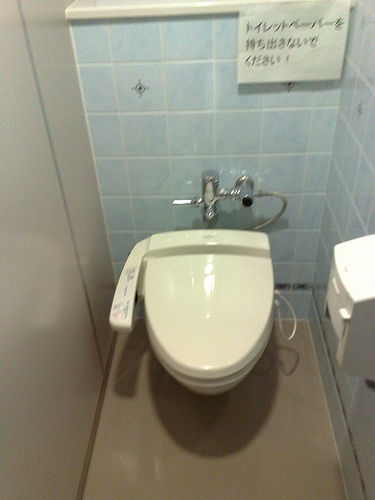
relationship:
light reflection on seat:
[195, 244, 222, 293] [138, 247, 275, 395]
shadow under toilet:
[152, 385, 273, 461] [91, 230, 304, 413]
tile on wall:
[173, 107, 315, 151] [86, 43, 369, 174]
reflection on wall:
[10, 242, 72, 325] [1, 195, 92, 457]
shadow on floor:
[152, 385, 273, 461] [109, 397, 318, 487]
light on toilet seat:
[189, 257, 219, 309] [127, 233, 309, 370]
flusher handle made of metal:
[172, 196, 205, 208] [166, 163, 282, 231]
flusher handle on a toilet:
[172, 196, 205, 208] [78, 150, 331, 488]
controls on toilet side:
[110, 242, 156, 337] [96, 228, 303, 399]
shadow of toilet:
[152, 385, 273, 461] [89, 222, 318, 412]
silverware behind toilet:
[156, 164, 310, 225] [70, 226, 313, 395]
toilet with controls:
[72, 199, 305, 403] [96, 220, 158, 333]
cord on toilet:
[269, 284, 314, 349] [64, 218, 300, 453]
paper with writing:
[244, 7, 353, 95] [246, 18, 331, 72]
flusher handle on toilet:
[160, 190, 211, 215] [89, 145, 330, 425]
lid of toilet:
[143, 246, 269, 389] [89, 180, 343, 440]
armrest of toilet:
[96, 249, 143, 329] [102, 220, 294, 402]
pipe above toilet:
[252, 180, 294, 237] [100, 200, 292, 407]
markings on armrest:
[106, 252, 143, 331] [108, 249, 142, 329]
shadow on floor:
[121, 385, 305, 460] [111, 395, 289, 495]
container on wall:
[308, 239, 372, 357] [298, 130, 373, 427]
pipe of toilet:
[252, 180, 289, 237] [78, 211, 326, 422]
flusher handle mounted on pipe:
[172, 196, 205, 208] [189, 164, 236, 239]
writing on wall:
[229, 16, 345, 85] [150, 5, 372, 189]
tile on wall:
[123, 112, 170, 159] [85, 41, 362, 233]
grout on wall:
[96, 143, 207, 175] [85, 41, 362, 233]